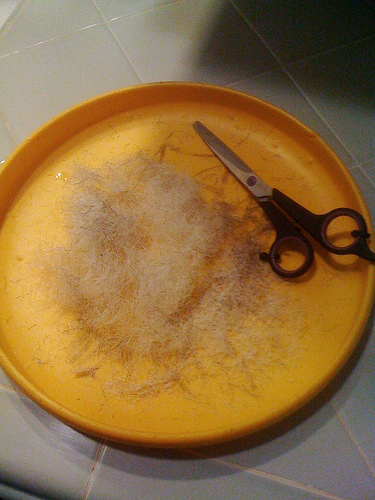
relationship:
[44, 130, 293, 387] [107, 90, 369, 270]
hairs on plate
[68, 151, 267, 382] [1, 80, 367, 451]
hairs on plate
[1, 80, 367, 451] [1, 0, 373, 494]
plate on tiles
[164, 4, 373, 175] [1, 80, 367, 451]
shadow on plate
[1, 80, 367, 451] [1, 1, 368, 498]
plate on tile